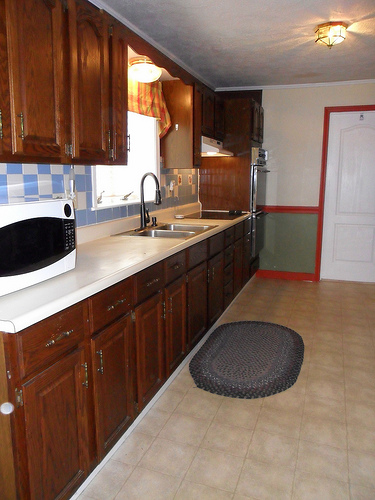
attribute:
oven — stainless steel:
[250, 145, 268, 256]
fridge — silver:
[260, 146, 278, 256]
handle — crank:
[96, 188, 106, 205]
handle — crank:
[121, 188, 134, 201]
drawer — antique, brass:
[17, 300, 86, 378]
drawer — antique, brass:
[87, 276, 133, 334]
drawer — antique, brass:
[136, 262, 164, 305]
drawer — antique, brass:
[163, 252, 189, 283]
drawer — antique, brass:
[223, 227, 236, 245]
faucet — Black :
[138, 169, 159, 227]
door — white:
[320, 107, 372, 283]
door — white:
[318, 105, 367, 282]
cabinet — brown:
[1, 1, 124, 163]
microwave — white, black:
[3, 185, 80, 283]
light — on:
[129, 58, 161, 82]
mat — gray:
[190, 320, 306, 400]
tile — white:
[282, 287, 328, 309]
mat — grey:
[188, 313, 308, 400]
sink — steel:
[138, 191, 239, 256]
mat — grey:
[205, 327, 298, 384]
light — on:
[310, 19, 354, 53]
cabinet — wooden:
[7, 348, 92, 498]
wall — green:
[252, 201, 324, 277]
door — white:
[321, 105, 374, 298]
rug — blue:
[183, 298, 308, 413]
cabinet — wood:
[21, 347, 90, 499]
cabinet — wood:
[89, 310, 137, 464]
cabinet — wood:
[135, 288, 165, 407]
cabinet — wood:
[163, 272, 184, 375]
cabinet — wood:
[186, 260, 207, 349]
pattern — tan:
[185, 404, 335, 486]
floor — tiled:
[83, 272, 374, 499]